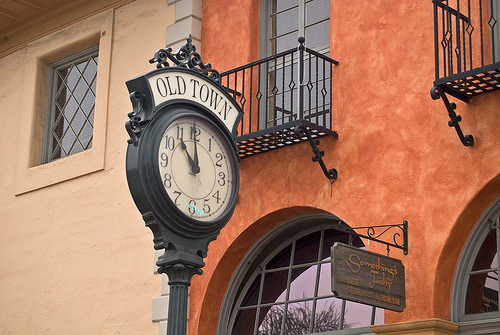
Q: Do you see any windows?
A: Yes, there is a window.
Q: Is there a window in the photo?
A: Yes, there is a window.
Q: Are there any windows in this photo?
A: Yes, there is a window.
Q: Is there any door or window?
A: Yes, there is a window.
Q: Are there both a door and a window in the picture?
A: No, there is a window but no doors.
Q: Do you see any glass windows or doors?
A: Yes, there is a glass window.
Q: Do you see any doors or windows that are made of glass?
A: Yes, the window is made of glass.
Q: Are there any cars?
A: No, there are no cars.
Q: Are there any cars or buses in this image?
A: No, there are no cars or buses.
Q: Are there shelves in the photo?
A: No, there are no shelves.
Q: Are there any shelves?
A: No, there are no shelves.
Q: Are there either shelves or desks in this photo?
A: No, there are no shelves or desks.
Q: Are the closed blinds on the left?
A: Yes, the blinds are on the left of the image.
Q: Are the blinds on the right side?
A: No, the blinds are on the left of the image.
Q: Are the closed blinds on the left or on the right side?
A: The blinds are on the left of the image.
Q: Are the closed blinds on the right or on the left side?
A: The blinds are on the left of the image.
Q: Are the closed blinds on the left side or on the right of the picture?
A: The blinds are on the left of the image.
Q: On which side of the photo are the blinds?
A: The blinds are on the left of the image.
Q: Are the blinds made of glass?
A: Yes, the blinds are made of glass.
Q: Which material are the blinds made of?
A: The blinds are made of glass.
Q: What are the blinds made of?
A: The blinds are made of glass.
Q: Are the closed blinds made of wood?
A: No, the blinds are made of glass.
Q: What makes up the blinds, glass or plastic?
A: The blinds are made of glass.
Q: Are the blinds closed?
A: Yes, the blinds are closed.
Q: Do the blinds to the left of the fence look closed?
A: Yes, the blinds are closed.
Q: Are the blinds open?
A: No, the blinds are closed.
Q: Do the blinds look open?
A: No, the blinds are closed.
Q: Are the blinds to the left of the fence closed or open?
A: The blinds are closed.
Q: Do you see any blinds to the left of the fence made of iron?
A: Yes, there are blinds to the left of the fence.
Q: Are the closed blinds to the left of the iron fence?
A: Yes, the blinds are to the left of the fence.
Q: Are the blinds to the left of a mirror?
A: No, the blinds are to the left of the fence.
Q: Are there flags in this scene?
A: No, there are no flags.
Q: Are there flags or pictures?
A: No, there are no flags or pictures.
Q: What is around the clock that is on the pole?
A: The frame is around the clock.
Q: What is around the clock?
A: The frame is around the clock.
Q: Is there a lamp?
A: No, there are no lamps.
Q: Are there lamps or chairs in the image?
A: No, there are no lamps or chairs.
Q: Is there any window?
A: Yes, there is a window.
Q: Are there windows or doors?
A: Yes, there is a window.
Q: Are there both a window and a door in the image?
A: No, there is a window but no doors.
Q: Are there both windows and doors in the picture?
A: No, there is a window but no doors.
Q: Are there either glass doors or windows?
A: Yes, there is a glass window.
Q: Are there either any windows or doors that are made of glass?
A: Yes, the window is made of glass.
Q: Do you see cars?
A: No, there are no cars.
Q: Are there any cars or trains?
A: No, there are no cars or trains.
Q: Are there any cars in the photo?
A: No, there are no cars.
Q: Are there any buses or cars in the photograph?
A: No, there are no cars or buses.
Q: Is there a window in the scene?
A: Yes, there is a window.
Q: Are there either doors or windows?
A: Yes, there is a window.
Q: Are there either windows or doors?
A: Yes, there is a window.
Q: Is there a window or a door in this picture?
A: Yes, there is a window.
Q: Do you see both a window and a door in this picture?
A: No, there is a window but no doors.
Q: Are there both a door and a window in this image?
A: No, there is a window but no doors.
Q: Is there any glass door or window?
A: Yes, there is a glass window.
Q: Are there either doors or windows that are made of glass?
A: Yes, the window is made of glass.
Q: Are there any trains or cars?
A: No, there are no cars or trains.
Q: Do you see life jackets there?
A: No, there are no life jackets.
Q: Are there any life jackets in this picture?
A: No, there are no life jackets.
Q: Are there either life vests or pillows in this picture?
A: No, there are no life vests or pillows.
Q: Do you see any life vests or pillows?
A: No, there are no life vests or pillows.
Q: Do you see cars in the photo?
A: No, there are no cars.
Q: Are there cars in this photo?
A: No, there are no cars.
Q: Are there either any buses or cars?
A: No, there are no cars or buses.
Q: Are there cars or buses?
A: No, there are no cars or buses.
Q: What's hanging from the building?
A: The sign is hanging from the building.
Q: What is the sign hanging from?
A: The sign is hanging from the building.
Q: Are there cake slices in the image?
A: No, there are no cake slices.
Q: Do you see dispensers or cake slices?
A: No, there are no cake slices or dispensers.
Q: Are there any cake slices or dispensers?
A: No, there are no cake slices or dispensers.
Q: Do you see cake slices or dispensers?
A: No, there are no cake slices or dispensers.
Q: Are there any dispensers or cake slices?
A: No, there are no cake slices or dispensers.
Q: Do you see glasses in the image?
A: No, there are no glasses.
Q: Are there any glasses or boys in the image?
A: No, there are no glasses or boys.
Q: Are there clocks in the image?
A: Yes, there is a clock.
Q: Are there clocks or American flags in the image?
A: Yes, there is a clock.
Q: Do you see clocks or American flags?
A: Yes, there is a clock.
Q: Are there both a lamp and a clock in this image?
A: No, there is a clock but no lamps.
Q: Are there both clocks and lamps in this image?
A: No, there is a clock but no lamps.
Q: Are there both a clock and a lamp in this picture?
A: No, there is a clock but no lamps.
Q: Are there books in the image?
A: No, there are no books.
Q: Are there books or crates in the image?
A: No, there are no books or crates.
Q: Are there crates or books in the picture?
A: No, there are no books or crates.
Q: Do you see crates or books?
A: No, there are no books or crates.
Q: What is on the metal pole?
A: The clock is on the pole.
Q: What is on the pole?
A: The clock is on the pole.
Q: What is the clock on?
A: The clock is on the pole.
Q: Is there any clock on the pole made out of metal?
A: Yes, there is a clock on the pole.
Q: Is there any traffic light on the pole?
A: No, there is a clock on the pole.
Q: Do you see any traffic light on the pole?
A: No, there is a clock on the pole.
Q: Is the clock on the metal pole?
A: Yes, the clock is on the pole.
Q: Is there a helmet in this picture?
A: No, there are no helmets.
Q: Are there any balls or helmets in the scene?
A: No, there are no helmets or balls.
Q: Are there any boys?
A: No, there are no boys.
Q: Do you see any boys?
A: No, there are no boys.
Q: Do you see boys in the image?
A: No, there are no boys.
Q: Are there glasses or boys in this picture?
A: No, there are no boys or glasses.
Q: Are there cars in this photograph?
A: No, there are no cars.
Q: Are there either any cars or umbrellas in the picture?
A: No, there are no cars or umbrellas.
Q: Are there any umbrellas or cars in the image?
A: No, there are no cars or umbrellas.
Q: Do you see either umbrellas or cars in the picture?
A: No, there are no cars or umbrellas.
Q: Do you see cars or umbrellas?
A: No, there are no cars or umbrellas.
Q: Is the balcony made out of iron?
A: Yes, the balcony is made of iron.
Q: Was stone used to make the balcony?
A: No, the balcony is made of iron.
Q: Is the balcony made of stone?
A: No, the balcony is made of iron.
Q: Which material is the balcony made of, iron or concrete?
A: The balcony is made of iron.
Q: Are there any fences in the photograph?
A: Yes, there is a fence.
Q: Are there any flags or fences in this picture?
A: Yes, there is a fence.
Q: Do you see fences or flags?
A: Yes, there is a fence.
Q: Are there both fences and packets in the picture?
A: No, there is a fence but no packets.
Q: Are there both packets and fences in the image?
A: No, there is a fence but no packets.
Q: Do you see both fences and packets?
A: No, there is a fence but no packets.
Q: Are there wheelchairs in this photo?
A: No, there are no wheelchairs.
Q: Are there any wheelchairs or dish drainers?
A: No, there are no wheelchairs or dish drainers.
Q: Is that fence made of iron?
A: Yes, the fence is made of iron.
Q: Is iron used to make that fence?
A: Yes, the fence is made of iron.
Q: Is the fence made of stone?
A: No, the fence is made of iron.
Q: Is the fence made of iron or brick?
A: The fence is made of iron.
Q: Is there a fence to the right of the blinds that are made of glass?
A: Yes, there is a fence to the right of the blinds.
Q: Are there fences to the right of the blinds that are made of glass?
A: Yes, there is a fence to the right of the blinds.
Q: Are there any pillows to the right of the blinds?
A: No, there is a fence to the right of the blinds.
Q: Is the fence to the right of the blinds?
A: Yes, the fence is to the right of the blinds.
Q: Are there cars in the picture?
A: No, there are no cars.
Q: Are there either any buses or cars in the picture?
A: No, there are no cars or buses.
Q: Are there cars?
A: No, there are no cars.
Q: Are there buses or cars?
A: No, there are no cars or buses.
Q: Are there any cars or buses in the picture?
A: No, there are no cars or buses.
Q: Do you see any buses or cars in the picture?
A: No, there are no cars or buses.